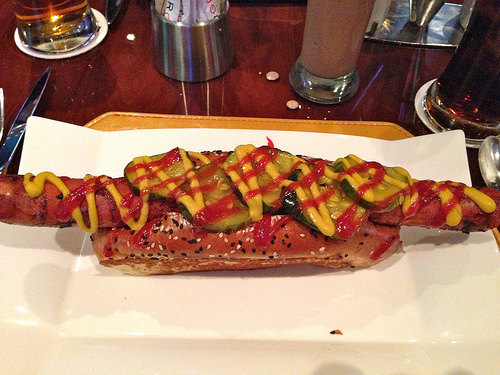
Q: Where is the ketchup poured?
A: On the meat.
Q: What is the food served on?
A: Paper.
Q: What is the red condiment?
A: Ketchup.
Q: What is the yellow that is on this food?
A: Mustard.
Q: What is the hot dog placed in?
A: Bun.